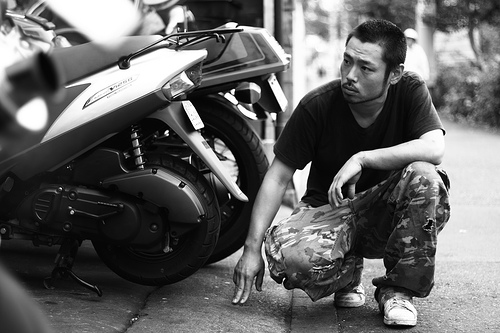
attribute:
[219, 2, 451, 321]
man — crouching, looking, bending down, kneeling, croutching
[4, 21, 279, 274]
bike — resting, dark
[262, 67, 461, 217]
t shirt — black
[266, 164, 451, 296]
pants — camouflage, camo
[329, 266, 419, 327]
sneakers — white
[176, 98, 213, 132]
license plate — white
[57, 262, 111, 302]
kick stand — down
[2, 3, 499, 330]
photo — white, black